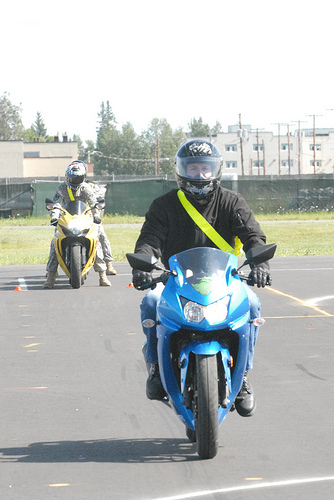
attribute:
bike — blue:
[124, 242, 277, 460]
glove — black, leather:
[245, 263, 271, 288]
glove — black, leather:
[130, 267, 156, 291]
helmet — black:
[173, 140, 223, 200]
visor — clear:
[173, 156, 222, 180]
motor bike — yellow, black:
[43, 195, 105, 288]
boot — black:
[144, 363, 169, 401]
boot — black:
[234, 373, 257, 418]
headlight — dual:
[181, 299, 228, 325]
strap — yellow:
[176, 188, 242, 255]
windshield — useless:
[171, 244, 234, 295]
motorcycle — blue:
[127, 243, 288, 455]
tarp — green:
[7, 177, 333, 213]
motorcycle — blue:
[123, 242, 275, 459]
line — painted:
[263, 283, 332, 316]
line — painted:
[259, 313, 332, 319]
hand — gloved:
[128, 267, 158, 289]